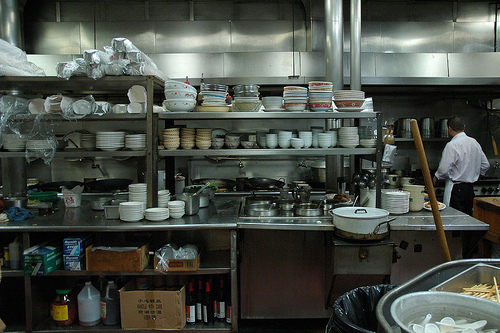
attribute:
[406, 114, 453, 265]
handle — leaning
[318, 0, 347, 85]
pole — metal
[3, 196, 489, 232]
counter — silver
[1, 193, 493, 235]
countertop — metal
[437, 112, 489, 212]
man — wearing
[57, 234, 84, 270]
box — double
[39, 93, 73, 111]
chinese cartons — empty, plastic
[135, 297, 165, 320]
lettering — black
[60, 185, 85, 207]
food carton — empty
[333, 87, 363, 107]
bowls — round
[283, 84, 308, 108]
bowls — stacked, round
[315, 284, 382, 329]
bag — black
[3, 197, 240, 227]
surface — large, metal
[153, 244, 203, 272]
box — containing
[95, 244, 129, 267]
box — brown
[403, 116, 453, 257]
pole — brown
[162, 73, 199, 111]
bowls — stacked, round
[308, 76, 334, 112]
bowls — stacked, round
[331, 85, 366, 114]
bowls — stacked, round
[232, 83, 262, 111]
bowls — stacked, round